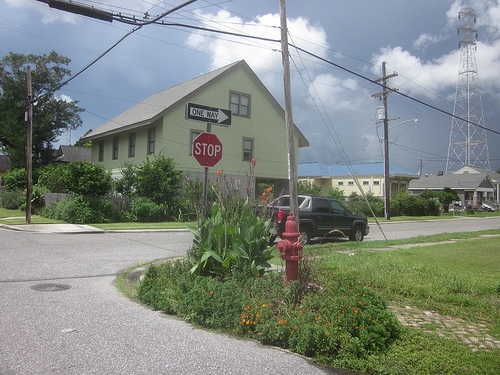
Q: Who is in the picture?
A: Nobody.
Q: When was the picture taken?
A: During the day.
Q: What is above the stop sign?
A: A one way sign.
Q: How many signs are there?
A: Two.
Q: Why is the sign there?
A: To control traffic.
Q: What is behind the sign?
A: A house.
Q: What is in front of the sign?
A: A plant.